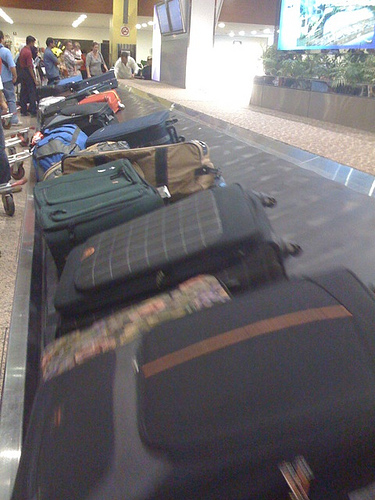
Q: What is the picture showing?
A: It is showing an airport.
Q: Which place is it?
A: It is an airport.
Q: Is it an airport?
A: Yes, it is an airport.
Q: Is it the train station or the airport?
A: It is the airport.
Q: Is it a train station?
A: No, it is an airport.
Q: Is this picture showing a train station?
A: No, the picture is showing an airport.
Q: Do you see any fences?
A: No, there are no fences.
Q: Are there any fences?
A: No, there are no fences.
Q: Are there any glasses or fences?
A: No, there are no fences or glasses.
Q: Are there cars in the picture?
A: No, there are no cars.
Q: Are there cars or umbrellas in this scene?
A: No, there are no cars or umbrellas.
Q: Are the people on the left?
A: Yes, the people are on the left of the image.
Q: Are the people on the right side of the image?
A: No, the people are on the left of the image.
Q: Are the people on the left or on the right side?
A: The people are on the left of the image.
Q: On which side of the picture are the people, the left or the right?
A: The people are on the left of the image.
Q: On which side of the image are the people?
A: The people are on the left of the image.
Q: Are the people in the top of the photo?
A: Yes, the people are in the top of the image.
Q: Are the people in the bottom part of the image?
A: No, the people are in the top of the image.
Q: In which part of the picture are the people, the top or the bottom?
A: The people are in the top of the image.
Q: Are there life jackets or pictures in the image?
A: No, there are no pictures or life jackets.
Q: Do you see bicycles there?
A: No, there are no bicycles.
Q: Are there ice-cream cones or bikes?
A: No, there are no bikes or ice-cream cones.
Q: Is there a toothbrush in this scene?
A: No, there are no toothbrushes.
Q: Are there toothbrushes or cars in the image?
A: No, there are no toothbrushes or cars.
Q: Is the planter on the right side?
A: Yes, the planter is on the right of the image.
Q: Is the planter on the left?
A: No, the planter is on the right of the image.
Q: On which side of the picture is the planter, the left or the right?
A: The planter is on the right of the image.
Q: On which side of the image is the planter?
A: The planter is on the right of the image.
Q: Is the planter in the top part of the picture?
A: Yes, the planter is in the top of the image.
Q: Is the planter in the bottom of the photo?
A: No, the planter is in the top of the image.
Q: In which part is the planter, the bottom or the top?
A: The planter is in the top of the image.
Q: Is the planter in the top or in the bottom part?
A: The planter is in the top of the image.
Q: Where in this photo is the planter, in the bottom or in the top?
A: The planter is in the top of the image.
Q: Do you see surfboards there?
A: No, there are no surfboards.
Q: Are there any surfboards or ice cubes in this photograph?
A: No, there are no surfboards or ice cubes.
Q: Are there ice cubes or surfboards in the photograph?
A: No, there are no surfboards or ice cubes.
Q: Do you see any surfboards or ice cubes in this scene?
A: No, there are no surfboards or ice cubes.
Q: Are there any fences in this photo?
A: No, there are no fences.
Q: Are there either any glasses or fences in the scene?
A: No, there are no fences or glasses.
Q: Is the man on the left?
A: Yes, the man is on the left of the image.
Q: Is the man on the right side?
A: No, the man is on the left of the image.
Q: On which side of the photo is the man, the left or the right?
A: The man is on the left of the image.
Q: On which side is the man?
A: The man is on the left of the image.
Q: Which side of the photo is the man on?
A: The man is on the left of the image.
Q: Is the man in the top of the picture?
A: Yes, the man is in the top of the image.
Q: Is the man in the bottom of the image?
A: No, the man is in the top of the image.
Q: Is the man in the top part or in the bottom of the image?
A: The man is in the top of the image.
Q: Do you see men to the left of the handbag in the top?
A: Yes, there is a man to the left of the handbag.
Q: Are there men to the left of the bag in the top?
A: Yes, there is a man to the left of the handbag.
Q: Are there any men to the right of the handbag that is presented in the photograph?
A: No, the man is to the left of the handbag.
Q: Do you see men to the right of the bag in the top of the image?
A: No, the man is to the left of the handbag.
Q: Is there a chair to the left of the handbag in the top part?
A: No, there is a man to the left of the handbag.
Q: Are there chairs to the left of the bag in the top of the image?
A: No, there is a man to the left of the handbag.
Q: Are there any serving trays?
A: No, there are no serving trays.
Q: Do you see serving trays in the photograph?
A: No, there are no serving trays.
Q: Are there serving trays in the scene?
A: No, there are no serving trays.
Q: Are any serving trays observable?
A: No, there are no serving trays.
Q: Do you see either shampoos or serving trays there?
A: No, there are no serving trays or shampoos.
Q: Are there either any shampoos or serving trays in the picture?
A: No, there are no serving trays or shampoos.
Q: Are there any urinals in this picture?
A: No, there are no urinals.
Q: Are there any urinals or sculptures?
A: No, there are no urinals or sculptures.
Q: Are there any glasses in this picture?
A: No, there are no glasses.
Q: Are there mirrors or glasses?
A: No, there are no glasses or mirrors.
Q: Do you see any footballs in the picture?
A: No, there are no footballs.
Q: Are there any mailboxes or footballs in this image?
A: No, there are no footballs or mailboxes.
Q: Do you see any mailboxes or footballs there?
A: No, there are no footballs or mailboxes.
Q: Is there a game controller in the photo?
A: No, there are no game controllers.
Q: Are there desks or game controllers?
A: No, there are no game controllers or desks.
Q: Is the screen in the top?
A: Yes, the screen is in the top of the image.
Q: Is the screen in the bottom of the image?
A: No, the screen is in the top of the image.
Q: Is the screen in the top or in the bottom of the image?
A: The screen is in the top of the image.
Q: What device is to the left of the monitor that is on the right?
A: The device is a screen.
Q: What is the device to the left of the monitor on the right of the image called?
A: The device is a screen.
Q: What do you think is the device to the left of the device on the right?
A: The device is a screen.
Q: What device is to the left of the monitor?
A: The device is a screen.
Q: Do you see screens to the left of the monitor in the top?
A: Yes, there is a screen to the left of the monitor.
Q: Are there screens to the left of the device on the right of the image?
A: Yes, there is a screen to the left of the monitor.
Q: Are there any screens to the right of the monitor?
A: No, the screen is to the left of the monitor.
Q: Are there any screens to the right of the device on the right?
A: No, the screen is to the left of the monitor.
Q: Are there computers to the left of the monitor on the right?
A: No, there is a screen to the left of the monitor.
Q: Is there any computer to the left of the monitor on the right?
A: No, there is a screen to the left of the monitor.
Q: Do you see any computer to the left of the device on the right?
A: No, there is a screen to the left of the monitor.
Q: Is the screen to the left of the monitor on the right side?
A: Yes, the screen is to the left of the monitor.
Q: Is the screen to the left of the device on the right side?
A: Yes, the screen is to the left of the monitor.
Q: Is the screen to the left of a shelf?
A: No, the screen is to the left of the monitor.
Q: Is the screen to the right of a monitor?
A: No, the screen is to the left of a monitor.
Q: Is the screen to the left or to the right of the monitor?
A: The screen is to the left of the monitor.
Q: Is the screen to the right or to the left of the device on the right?
A: The screen is to the left of the monitor.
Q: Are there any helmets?
A: No, there are no helmets.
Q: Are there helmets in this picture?
A: No, there are no helmets.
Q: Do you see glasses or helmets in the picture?
A: No, there are no helmets or glasses.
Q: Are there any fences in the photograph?
A: No, there are no fences.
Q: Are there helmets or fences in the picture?
A: No, there are no fences or helmets.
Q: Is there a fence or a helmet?
A: No, there are no fences or helmets.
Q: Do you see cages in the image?
A: No, there are no cages.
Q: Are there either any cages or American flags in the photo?
A: No, there are no cages or American flags.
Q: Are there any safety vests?
A: No, there are no safety vests.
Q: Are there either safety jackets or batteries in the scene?
A: No, there are no safety jackets or batteries.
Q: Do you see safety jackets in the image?
A: No, there are no safety jackets.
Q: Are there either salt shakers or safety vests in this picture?
A: No, there are no safety vests or salt shakers.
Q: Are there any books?
A: No, there are no books.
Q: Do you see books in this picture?
A: No, there are no books.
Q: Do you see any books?
A: No, there are no books.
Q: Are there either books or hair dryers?
A: No, there are no books or hair dryers.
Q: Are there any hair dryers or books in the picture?
A: No, there are no books or hair dryers.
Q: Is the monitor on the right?
A: Yes, the monitor is on the right of the image.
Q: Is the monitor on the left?
A: No, the monitor is on the right of the image.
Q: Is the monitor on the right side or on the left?
A: The monitor is on the right of the image.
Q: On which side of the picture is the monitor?
A: The monitor is on the right of the image.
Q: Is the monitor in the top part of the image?
A: Yes, the monitor is in the top of the image.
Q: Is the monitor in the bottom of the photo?
A: No, the monitor is in the top of the image.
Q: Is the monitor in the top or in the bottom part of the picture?
A: The monitor is in the top of the image.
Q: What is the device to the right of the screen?
A: The device is a monitor.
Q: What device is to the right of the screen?
A: The device is a monitor.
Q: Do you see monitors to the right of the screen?
A: Yes, there is a monitor to the right of the screen.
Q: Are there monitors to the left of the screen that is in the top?
A: No, the monitor is to the right of the screen.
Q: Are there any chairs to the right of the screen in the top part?
A: No, there is a monitor to the right of the screen.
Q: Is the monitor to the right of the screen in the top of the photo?
A: Yes, the monitor is to the right of the screen.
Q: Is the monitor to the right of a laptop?
A: No, the monitor is to the right of the screen.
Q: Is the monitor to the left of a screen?
A: No, the monitor is to the right of a screen.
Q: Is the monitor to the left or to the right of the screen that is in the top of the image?
A: The monitor is to the right of the screen.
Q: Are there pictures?
A: No, there are no pictures.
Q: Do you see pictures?
A: No, there are no pictures.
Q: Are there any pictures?
A: No, there are no pictures.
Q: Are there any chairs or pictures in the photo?
A: No, there are no pictures or chairs.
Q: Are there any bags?
A: Yes, there is a bag.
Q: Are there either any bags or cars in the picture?
A: Yes, there is a bag.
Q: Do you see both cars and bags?
A: No, there is a bag but no cars.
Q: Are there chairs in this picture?
A: No, there are no chairs.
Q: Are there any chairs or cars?
A: No, there are no chairs or cars.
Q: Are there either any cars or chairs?
A: No, there are no chairs or cars.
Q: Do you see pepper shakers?
A: No, there are no pepper shakers.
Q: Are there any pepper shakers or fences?
A: No, there are no pepper shakers or fences.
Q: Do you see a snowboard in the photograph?
A: No, there are no snowboards.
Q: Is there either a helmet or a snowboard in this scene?
A: No, there are no snowboards or helmets.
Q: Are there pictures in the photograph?
A: No, there are no pictures.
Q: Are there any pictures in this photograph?
A: No, there are no pictures.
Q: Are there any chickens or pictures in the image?
A: No, there are no pictures or chickens.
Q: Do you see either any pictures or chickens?
A: No, there are no pictures or chickens.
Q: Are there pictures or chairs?
A: No, there are no pictures or chairs.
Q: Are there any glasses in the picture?
A: No, there are no glasses.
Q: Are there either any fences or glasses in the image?
A: No, there are no glasses or fences.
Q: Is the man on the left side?
A: Yes, the man is on the left of the image.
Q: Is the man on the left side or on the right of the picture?
A: The man is on the left of the image.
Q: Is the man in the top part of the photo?
A: Yes, the man is in the top of the image.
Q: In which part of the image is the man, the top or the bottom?
A: The man is in the top of the image.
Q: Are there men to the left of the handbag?
A: Yes, there is a man to the left of the handbag.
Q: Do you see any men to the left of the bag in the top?
A: Yes, there is a man to the left of the handbag.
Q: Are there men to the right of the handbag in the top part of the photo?
A: No, the man is to the left of the handbag.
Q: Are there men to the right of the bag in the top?
A: No, the man is to the left of the handbag.